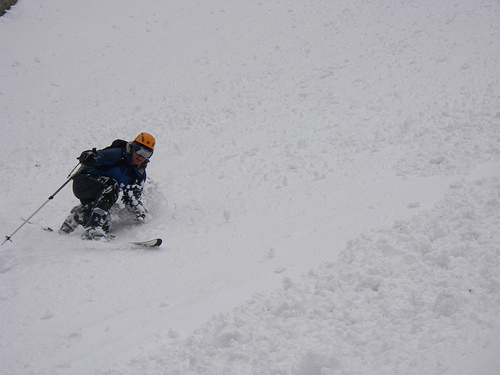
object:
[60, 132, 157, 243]
man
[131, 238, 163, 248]
skis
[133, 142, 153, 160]
goggles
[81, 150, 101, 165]
skier's hand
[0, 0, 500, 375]
snow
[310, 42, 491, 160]
mountain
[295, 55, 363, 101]
fluffy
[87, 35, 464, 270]
scene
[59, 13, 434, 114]
day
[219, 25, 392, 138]
hillside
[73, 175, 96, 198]
black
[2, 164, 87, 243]
pole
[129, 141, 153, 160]
pair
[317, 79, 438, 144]
ground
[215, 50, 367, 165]
place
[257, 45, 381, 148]
ski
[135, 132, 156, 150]
cap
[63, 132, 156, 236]
snowsuit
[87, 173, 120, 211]
pants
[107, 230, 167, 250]
white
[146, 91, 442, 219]
down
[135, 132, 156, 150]
yellow